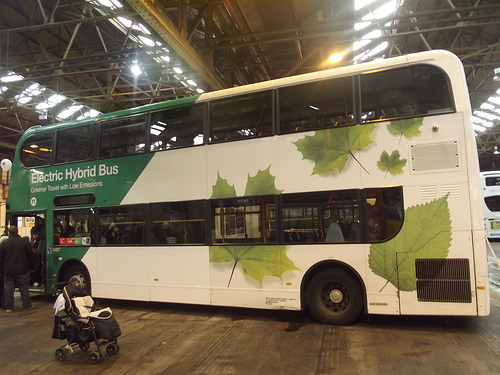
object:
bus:
[5, 48, 488, 327]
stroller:
[51, 276, 120, 364]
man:
[0, 223, 35, 314]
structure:
[1, 1, 500, 374]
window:
[16, 130, 56, 169]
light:
[129, 64, 144, 75]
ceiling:
[2, 0, 499, 149]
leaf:
[363, 190, 455, 291]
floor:
[3, 292, 500, 375]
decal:
[27, 161, 119, 184]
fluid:
[280, 315, 306, 332]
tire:
[302, 265, 366, 326]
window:
[52, 123, 101, 167]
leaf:
[374, 148, 405, 179]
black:
[0, 235, 33, 279]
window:
[98, 114, 149, 160]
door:
[5, 210, 49, 291]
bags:
[51, 313, 72, 339]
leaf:
[289, 124, 381, 177]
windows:
[354, 62, 458, 126]